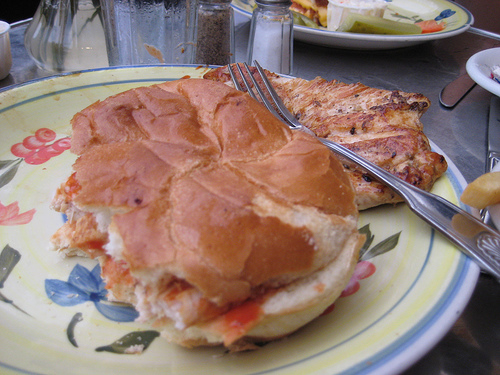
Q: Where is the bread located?
A: On the plate.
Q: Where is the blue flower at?
A: On the plate.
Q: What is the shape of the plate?
A: Round.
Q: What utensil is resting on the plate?
A: Fork.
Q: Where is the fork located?
A: Resting on the plate.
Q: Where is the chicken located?
A: On the plate.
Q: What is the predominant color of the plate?
A: Yellow.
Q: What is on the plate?
A: Food.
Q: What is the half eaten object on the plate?
A: Sandwich.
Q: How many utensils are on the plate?
A: One.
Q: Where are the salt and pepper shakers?
A: Behind the plate.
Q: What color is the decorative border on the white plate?
A: Blue.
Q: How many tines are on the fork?
A: Four.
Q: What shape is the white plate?
A: Round.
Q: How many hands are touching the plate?
A: None.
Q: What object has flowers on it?
A: Plate.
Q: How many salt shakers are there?
A: One.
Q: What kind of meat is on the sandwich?
A: Chicken.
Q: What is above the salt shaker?
A: Another plate.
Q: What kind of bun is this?
A: Hamburger bun.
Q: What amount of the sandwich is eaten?
A: About one fourth.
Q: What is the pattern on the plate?
A: Floral.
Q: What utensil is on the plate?
A: A fork.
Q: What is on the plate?
A: A chicken sandwich.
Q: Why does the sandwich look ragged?
A: There are bites taken out of it.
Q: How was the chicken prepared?
A: Grilled.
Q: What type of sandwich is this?
A: Chicken.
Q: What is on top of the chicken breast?
A: A fork.